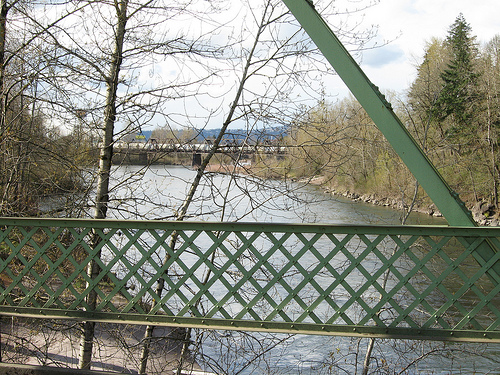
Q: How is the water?
A: Calm.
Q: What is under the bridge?
A: Water.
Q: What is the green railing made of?
A: Metal.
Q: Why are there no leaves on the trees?
A: It is early spring.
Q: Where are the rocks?
A: On the shoreline.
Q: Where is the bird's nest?
A: There is no bird's nest.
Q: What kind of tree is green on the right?
A: Pine.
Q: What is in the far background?
A: Hills.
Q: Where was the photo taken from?
A: A bridge.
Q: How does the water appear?
A: Calm.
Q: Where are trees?
A: Behind the fence.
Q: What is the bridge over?
A: A river.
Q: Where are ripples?
A: In the water.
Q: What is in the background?
A: A bridge.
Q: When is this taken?
A: During the day.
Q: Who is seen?
A: No one.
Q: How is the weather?
A: Clear.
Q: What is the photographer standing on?
A: A bridge.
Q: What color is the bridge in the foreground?
A: Green.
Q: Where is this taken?
A: From a bridge.